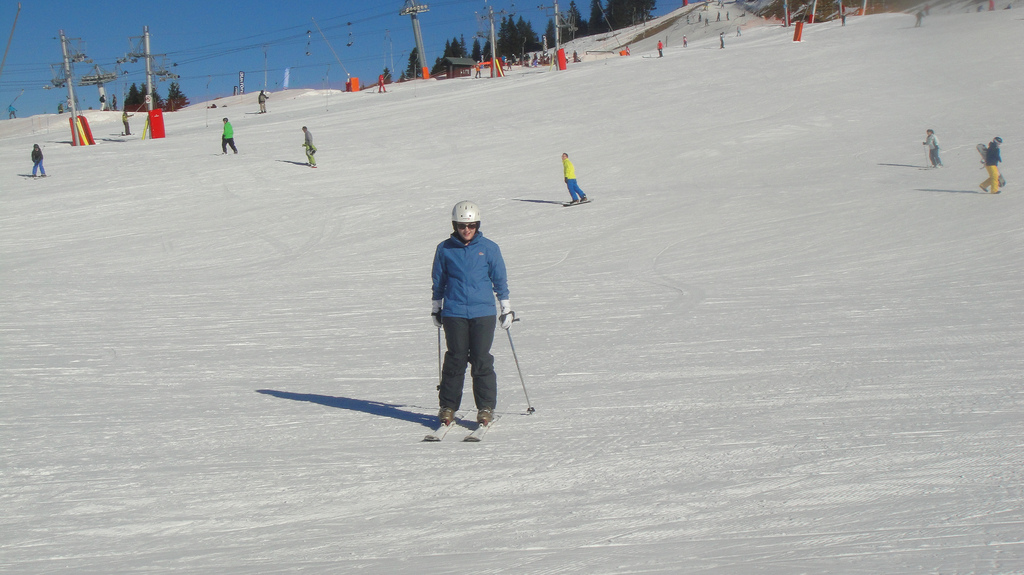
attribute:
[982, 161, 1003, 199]
pants — yellow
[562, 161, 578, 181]
jacket — yellow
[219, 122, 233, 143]
jacket — green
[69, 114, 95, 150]
pad — red and yellow